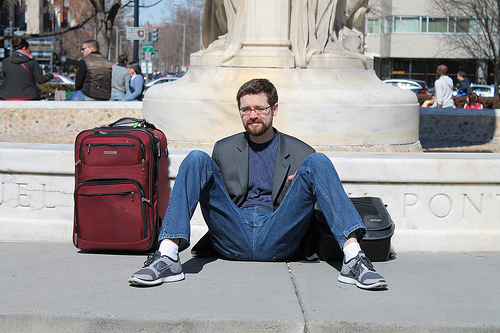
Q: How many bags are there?
A: Two.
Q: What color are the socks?
A: White.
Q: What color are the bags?
A: Red and grey.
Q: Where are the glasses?
A: On the man's face.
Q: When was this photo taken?
A: Daytime.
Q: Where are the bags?
A: On the ground.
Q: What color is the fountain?
A: White.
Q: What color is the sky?
A: Blue.